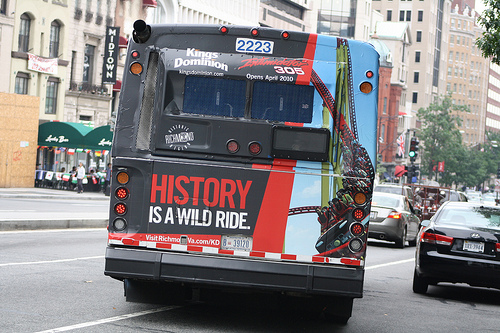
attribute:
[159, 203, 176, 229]
word — white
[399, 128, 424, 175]
light — green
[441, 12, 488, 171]
building — tan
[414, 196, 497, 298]
car — black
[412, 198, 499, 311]
car — black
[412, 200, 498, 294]
car — black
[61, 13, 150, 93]
sign — black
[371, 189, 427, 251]
car — silver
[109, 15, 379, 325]
bus — red, blue